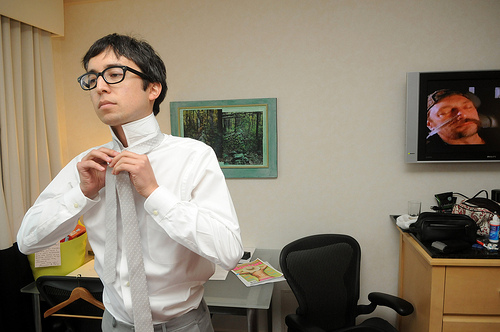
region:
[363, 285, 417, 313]
arm of the chair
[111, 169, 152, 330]
tie on the shirt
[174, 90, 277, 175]
print on the wall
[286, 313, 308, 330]
arm of the chair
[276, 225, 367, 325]
back of the chair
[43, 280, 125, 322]
wooden coat hanger on side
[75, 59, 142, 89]
glasses on the boy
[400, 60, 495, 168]
tv on the wall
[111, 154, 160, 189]
hand of the boy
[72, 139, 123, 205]
hand of the boy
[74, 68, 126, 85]
BOY WEARING EYE GLASSES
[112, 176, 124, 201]
BOY PUTTING A GREY TIE ON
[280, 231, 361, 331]
BLACK CHAIR IN THE CORNER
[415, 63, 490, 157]
TV IS ON THE WALL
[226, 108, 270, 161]
PICTURE ON THE WALL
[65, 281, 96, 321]
HANGER IS ON THE BACK OF CHAIR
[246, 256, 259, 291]
PAPER ON THE TABLE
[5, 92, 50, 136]
TAN CURTAINS ARE CLOSED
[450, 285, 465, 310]
CHEST IS MADE OUT OF WOOD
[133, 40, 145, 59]
BOY HAS SHORT BLACK HAIR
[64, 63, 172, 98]
man is wearing glasses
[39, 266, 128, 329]
clothes hanger is hanging on the desk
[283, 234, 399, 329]
computer desk is next to the table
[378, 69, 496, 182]
television is above the cabinet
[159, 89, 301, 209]
picture on the wall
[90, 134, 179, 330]
man is tying a tie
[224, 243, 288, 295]
magazine on the table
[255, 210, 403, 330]
computer chair is black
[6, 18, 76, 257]
curtains on the window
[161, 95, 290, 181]
picture frame is green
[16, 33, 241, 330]
A man putting on a tie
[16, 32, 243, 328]
A man wearing eyeglasses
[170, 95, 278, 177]
A framed picture hanging on the wall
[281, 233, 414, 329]
A black chair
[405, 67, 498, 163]
A screen mounted on the wall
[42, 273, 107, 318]
A wooden clothes hanger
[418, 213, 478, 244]
A shaving kit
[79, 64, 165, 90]
Black thick rimmed glasses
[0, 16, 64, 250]
Cream colored curtains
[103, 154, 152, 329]
A neck tie that hasn't been finished tying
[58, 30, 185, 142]
man wearing pair of glasses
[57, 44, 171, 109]
glasses are matte black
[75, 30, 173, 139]
man has black hair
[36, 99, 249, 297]
man wearing white shirt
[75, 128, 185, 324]
man tying a tie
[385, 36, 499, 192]
television with mans face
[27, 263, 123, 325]
coat hanger on back of chair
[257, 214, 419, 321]
office chair is black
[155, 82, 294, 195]
picture hanging on wall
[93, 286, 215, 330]
man wear grey bottoms